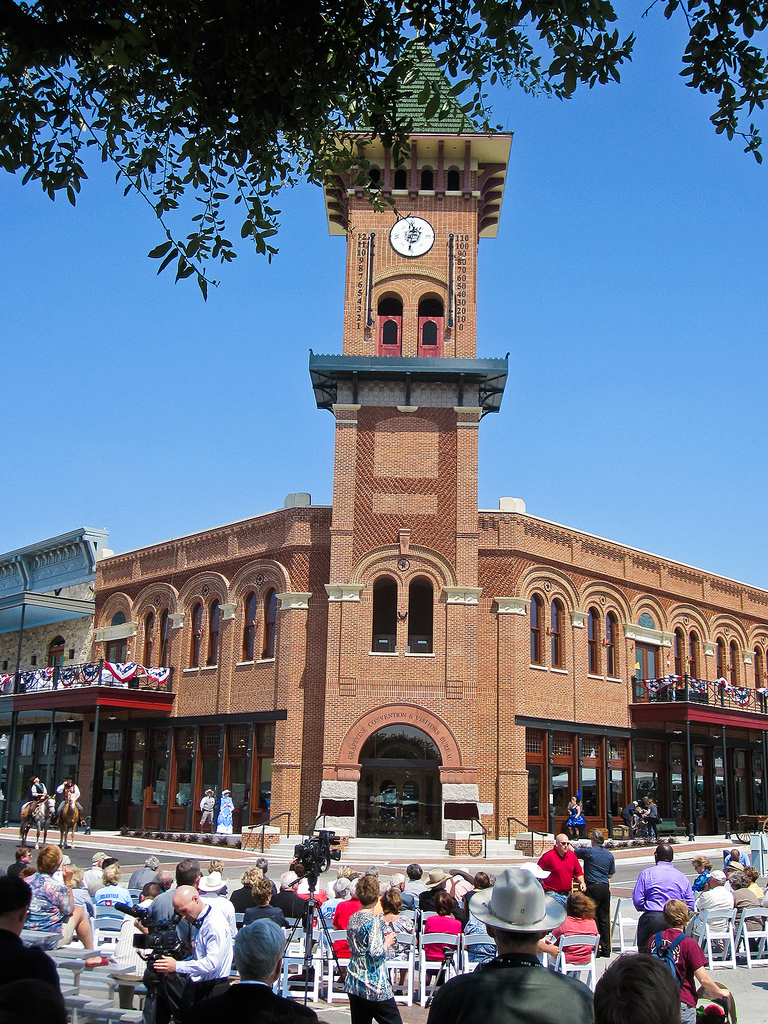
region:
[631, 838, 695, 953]
man wearing purple shirt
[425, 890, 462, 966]
person wearing pink shirt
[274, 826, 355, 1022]
video camera on tripod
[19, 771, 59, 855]
person riding a horse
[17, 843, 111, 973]
woman wearing red shoes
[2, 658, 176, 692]
bannister with american flag banners on rail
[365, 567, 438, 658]
pair of arched windows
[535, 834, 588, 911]
man wearing red shirt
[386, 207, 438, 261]
clock on tower of building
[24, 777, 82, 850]
Two men riding two horses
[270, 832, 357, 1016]
Camera to record video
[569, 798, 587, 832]
Woman wearing old fashion blue dress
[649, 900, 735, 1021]
man wearing a blue backpack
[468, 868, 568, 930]
White cowboy hat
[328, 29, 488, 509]
Tall brick clock tower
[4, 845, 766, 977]
Crowd waiting for a show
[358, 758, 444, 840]
Entrance into the building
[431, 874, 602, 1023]
man wearing cowboy hat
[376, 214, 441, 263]
black and white clock in brown tower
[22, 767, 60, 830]
rider on brown horse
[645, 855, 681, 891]
purple shirt worn by man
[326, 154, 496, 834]
brown and red clock tower in building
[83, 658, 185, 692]
red white and blue decorations on building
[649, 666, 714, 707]
red white and blue decorations on building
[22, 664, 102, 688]
red white and blue decorations on building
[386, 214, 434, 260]
a clock in on the tower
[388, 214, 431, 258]
the clock has a white background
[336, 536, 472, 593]
an arch is on the tower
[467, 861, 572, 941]
the man is wearing a hat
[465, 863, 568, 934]
the hat is white in color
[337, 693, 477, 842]
the tower has an arched entrance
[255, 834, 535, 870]
steps lead up to the entrance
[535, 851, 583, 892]
the man is wearing a short sleeve shirt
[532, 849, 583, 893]
the shirt is red in color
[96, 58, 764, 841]
the building is made of brick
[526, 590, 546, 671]
A window on a building.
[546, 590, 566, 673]
A window on a building.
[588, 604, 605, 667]
A window on a building.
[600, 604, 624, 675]
A window on a building.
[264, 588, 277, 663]
A window on a building.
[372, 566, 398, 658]
A window on a building.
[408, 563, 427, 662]
A window on a building.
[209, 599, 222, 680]
A window on a building.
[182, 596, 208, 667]
A window on a building.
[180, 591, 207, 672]
window on the side of the building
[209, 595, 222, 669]
window on the side of the building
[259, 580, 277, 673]
window on the side of the building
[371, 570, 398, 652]
window on the side of the building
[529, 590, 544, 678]
window on the side of the building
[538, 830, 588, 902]
man wearing a red shirt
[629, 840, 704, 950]
man wearing a purple shirt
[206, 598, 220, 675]
window on the side of brick building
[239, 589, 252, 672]
window on the side of brick building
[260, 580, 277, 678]
window on the side of brick building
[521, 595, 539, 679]
window on the side of brick building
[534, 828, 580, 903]
man in a red shirt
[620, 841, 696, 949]
man in a purple shirt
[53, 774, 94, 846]
person on a horse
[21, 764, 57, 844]
man on a horse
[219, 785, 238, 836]
woman in a blue dress